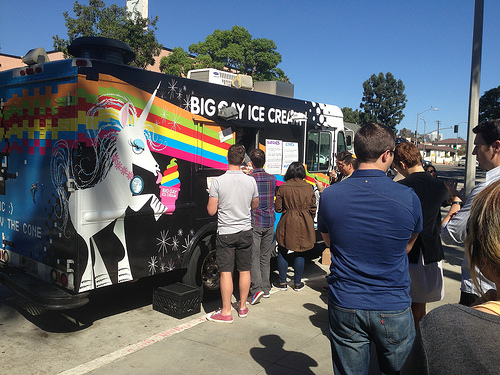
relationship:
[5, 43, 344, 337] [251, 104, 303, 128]
truck for ice cream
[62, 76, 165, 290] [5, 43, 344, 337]
unicorn on truck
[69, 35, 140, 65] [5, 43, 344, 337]
vent on truck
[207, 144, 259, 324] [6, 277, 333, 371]
people on pavement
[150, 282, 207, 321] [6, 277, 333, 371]
crate on pavement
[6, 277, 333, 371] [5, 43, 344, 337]
pavement beside truck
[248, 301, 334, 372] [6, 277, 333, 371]
shadow on pavement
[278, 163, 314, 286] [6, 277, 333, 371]
person on pavement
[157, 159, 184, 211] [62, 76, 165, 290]
ice cream cone for unicorn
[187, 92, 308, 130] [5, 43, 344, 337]
letters on truck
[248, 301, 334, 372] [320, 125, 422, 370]
shadow of person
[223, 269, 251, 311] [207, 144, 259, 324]
legs on people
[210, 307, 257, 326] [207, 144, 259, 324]
shoes on people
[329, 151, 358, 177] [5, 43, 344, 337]
face near truck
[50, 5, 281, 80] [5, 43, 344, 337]
trees behind truck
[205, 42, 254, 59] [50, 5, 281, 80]
leaves on trees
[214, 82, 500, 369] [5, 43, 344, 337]
people near truck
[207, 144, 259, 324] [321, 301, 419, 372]
people in jeans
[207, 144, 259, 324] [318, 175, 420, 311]
people in shirt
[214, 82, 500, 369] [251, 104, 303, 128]
people want ice cream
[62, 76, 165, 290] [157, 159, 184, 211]
unicorn eating ice cream cone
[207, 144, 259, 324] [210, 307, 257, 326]
people wearing shoes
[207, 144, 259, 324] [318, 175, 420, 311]
people wearing shirt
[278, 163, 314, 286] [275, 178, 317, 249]
person wearing coat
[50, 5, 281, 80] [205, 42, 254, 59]
trees have leaves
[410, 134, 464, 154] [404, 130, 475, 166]
roofs on houses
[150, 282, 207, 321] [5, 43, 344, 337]
crate beside truck